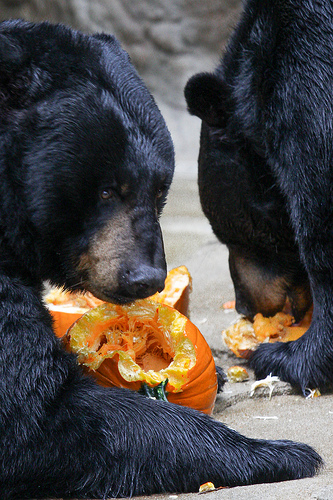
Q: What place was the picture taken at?
A: It was taken at the zoo.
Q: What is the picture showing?
A: It is showing a zoo.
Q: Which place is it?
A: It is a zoo.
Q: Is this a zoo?
A: Yes, it is a zoo.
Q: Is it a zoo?
A: Yes, it is a zoo.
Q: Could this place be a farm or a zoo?
A: It is a zoo.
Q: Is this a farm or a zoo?
A: It is a zoo.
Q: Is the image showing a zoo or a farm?
A: It is showing a zoo.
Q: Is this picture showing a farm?
A: No, the picture is showing a zoo.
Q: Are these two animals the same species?
A: Yes, all the animals are bears.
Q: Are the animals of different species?
A: No, all the animals are bears.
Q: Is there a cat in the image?
A: No, there are no cats.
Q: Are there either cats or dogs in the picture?
A: No, there are no cats or dogs.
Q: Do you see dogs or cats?
A: No, there are no cats or dogs.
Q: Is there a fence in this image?
A: No, there are no fences.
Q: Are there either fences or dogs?
A: No, there are no fences or dogs.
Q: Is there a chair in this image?
A: No, there are no chairs.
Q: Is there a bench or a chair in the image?
A: No, there are no chairs or benches.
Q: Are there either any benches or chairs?
A: No, there are no chairs or benches.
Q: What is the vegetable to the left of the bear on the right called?
A: The vegetable is a pumpkin.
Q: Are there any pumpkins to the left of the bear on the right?
A: Yes, there is a pumpkin to the left of the bear.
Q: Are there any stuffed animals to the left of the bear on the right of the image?
A: No, there is a pumpkin to the left of the bear.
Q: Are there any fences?
A: No, there are no fences.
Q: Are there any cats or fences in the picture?
A: No, there are no fences or cats.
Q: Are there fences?
A: No, there are no fences.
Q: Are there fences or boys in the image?
A: No, there are no fences or boys.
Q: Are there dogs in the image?
A: No, there are no dogs.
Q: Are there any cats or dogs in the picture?
A: No, there are no dogs or cats.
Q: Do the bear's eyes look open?
A: Yes, the eyes are open.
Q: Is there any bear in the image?
A: Yes, there is a bear.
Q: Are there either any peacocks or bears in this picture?
A: Yes, there is a bear.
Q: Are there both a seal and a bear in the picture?
A: No, there is a bear but no seals.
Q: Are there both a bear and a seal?
A: No, there is a bear but no seals.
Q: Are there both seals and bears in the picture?
A: No, there is a bear but no seals.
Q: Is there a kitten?
A: No, there are no kittens.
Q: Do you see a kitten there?
A: No, there are no kittens.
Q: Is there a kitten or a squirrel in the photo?
A: No, there are no kittens or squirrels.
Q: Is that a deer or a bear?
A: That is a bear.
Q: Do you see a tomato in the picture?
A: No, there are no tomatoes.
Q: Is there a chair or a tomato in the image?
A: No, there are no tomatoes or chairs.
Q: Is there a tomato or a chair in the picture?
A: No, there are no tomatoes or chairs.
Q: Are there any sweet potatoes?
A: No, there are no sweet potatoes.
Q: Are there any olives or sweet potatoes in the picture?
A: No, there are no sweet potatoes or olives.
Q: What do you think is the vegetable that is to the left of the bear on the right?
A: The vegetable is a pumpkin.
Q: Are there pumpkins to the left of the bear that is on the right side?
A: Yes, there is a pumpkin to the left of the bear.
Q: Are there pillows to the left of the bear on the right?
A: No, there is a pumpkin to the left of the bear.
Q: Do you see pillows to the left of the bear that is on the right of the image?
A: No, there is a pumpkin to the left of the bear.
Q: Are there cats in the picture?
A: No, there are no cats.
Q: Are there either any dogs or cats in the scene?
A: No, there are no cats or dogs.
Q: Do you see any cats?
A: No, there are no cats.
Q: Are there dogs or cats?
A: No, there are no cats or dogs.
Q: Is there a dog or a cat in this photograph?
A: No, there are no cats or dogs.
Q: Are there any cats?
A: No, there are no cats.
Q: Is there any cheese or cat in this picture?
A: No, there are no cats or cheese.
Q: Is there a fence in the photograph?
A: No, there are no fences.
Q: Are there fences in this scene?
A: No, there are no fences.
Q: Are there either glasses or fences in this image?
A: No, there are no fences or glasses.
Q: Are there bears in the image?
A: Yes, there is a bear.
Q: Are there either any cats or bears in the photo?
A: Yes, there is a bear.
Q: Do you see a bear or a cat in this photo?
A: Yes, there is a bear.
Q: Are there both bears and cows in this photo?
A: No, there is a bear but no cows.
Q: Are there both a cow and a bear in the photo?
A: No, there is a bear but no cows.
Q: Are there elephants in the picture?
A: No, there are no elephants.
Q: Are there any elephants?
A: No, there are no elephants.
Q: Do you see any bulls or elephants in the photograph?
A: No, there are no elephants or bulls.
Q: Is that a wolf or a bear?
A: That is a bear.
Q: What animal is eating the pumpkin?
A: The bear is eating the pumpkin.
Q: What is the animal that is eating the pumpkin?
A: The animal is a bear.